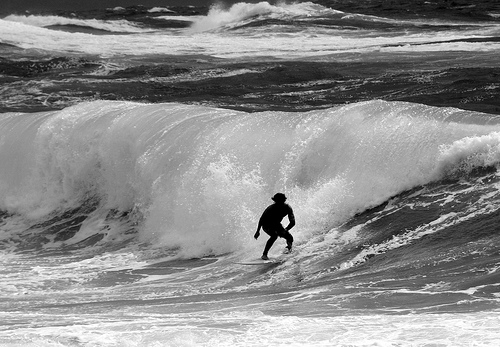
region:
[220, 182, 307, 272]
Surfer riding the waves.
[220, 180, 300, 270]
Surfing in the ocean.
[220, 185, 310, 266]
Surfer riding waves in the sea.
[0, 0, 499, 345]
Choppy waters in the ocean.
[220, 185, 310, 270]
Surfer standing on board riding waves.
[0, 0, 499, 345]
Wavy and choppy ocean water.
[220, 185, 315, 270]
Surfing the ocean water.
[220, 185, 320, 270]
Standing on surfboard in the ocean.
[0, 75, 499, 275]
Surfing with the current.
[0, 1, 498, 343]
Surfing the choppy ocean water.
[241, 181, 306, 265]
the person is surfing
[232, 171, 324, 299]
the person is surfing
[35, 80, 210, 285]
a wave of the sea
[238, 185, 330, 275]
A man surfing a wave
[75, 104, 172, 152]
this is a wave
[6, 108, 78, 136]
this is a wave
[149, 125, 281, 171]
this is a wave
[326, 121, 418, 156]
this is a wave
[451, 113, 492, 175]
this is a wave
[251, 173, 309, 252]
this is a person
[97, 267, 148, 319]
this is steered water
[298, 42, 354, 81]
the sky is dark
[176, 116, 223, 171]
THIS IS A WAVE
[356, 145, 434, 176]
THIS IS A WAVE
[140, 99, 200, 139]
THIS IS A WAVE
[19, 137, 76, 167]
THIS IS A WAVE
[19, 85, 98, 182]
THIS IS A WAVE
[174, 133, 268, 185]
THIS IS A WAVE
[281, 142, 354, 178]
THIS IS A WAVE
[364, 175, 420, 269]
THIS IS A WAVE